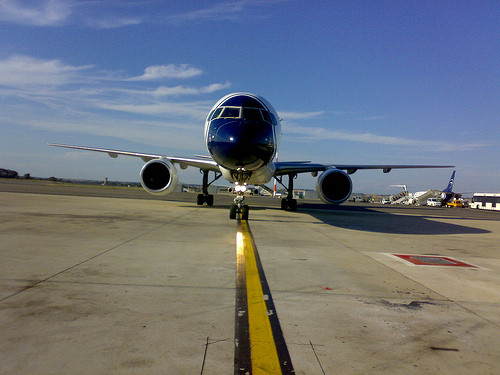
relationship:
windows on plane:
[206, 104, 276, 120] [43, 91, 456, 216]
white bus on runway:
[472, 189, 499, 209] [1, 165, 497, 370]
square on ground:
[389, 253, 473, 268] [268, 217, 497, 372]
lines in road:
[218, 213, 303, 373] [0, 188, 499, 371]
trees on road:
[2, 166, 30, 178] [1, 176, 276, 208]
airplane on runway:
[80, 74, 458, 214] [1, 165, 497, 370]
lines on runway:
[218, 213, 303, 373] [2, 210, 490, 373]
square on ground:
[389, 253, 473, 268] [395, 249, 475, 267]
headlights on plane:
[230, 182, 249, 196] [43, 91, 456, 216]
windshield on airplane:
[215, 102, 242, 128] [3, 96, 455, 210]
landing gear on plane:
[229, 204, 251, 220] [43, 91, 456, 216]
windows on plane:
[206, 104, 276, 120] [71, 29, 498, 279]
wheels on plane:
[195, 191, 296, 220] [43, 73, 458, 230]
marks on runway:
[367, 289, 441, 321] [1, 165, 497, 370]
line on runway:
[2, 272, 498, 306] [1, 165, 497, 370]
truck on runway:
[441, 199, 463, 211] [2, 210, 490, 373]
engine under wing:
[309, 154, 371, 218] [42, 134, 227, 180]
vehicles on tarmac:
[419, 191, 467, 212] [2, 168, 498, 237]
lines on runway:
[218, 213, 303, 373] [110, 189, 460, 374]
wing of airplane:
[35, 132, 220, 179] [51, 0, 456, 161]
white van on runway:
[426, 198, 441, 206] [2, 210, 490, 373]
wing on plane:
[35, 132, 220, 179] [32, 54, 471, 240]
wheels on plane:
[195, 191, 296, 220] [57, 67, 461, 219]